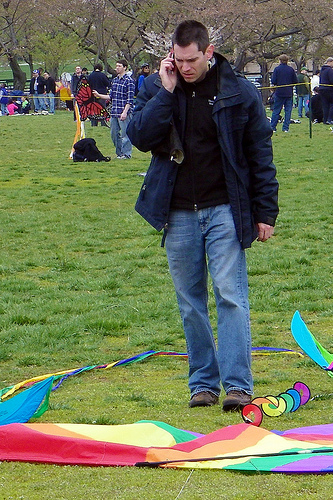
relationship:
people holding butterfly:
[89, 59, 135, 161] [72, 71, 110, 123]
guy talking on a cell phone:
[108, 21, 266, 263] [160, 41, 186, 82]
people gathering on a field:
[12, 68, 65, 124] [3, 56, 329, 497]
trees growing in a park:
[0, 2, 148, 99] [3, 0, 332, 498]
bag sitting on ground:
[65, 133, 111, 167] [2, 62, 331, 498]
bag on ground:
[65, 133, 111, 167] [2, 62, 331, 498]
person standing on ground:
[126, 18, 279, 410] [31, 323, 327, 486]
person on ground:
[126, 18, 279, 410] [31, 323, 327, 486]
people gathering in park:
[89, 59, 136, 160] [3, 0, 332, 498]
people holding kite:
[89, 59, 135, 161] [68, 72, 115, 122]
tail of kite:
[243, 380, 312, 426] [1, 347, 332, 473]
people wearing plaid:
[89, 59, 135, 161] [110, 73, 129, 116]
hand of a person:
[160, 51, 179, 93] [126, 18, 279, 410]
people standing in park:
[271, 48, 330, 127] [3, 0, 332, 498]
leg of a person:
[161, 215, 225, 413] [126, 18, 279, 410]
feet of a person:
[182, 384, 263, 412] [126, 18, 279, 410]